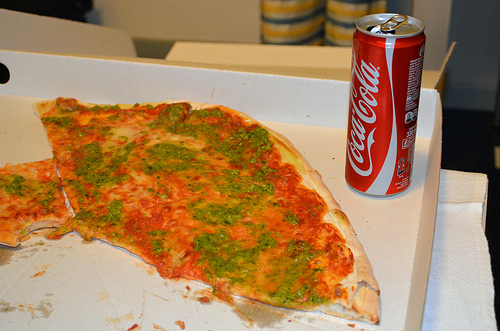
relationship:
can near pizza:
[343, 9, 420, 199] [1, 97, 381, 327]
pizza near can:
[1, 97, 381, 327] [343, 9, 420, 199]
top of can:
[380, 10, 409, 35] [343, 9, 420, 199]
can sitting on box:
[343, 9, 420, 199] [1, 47, 446, 330]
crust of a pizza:
[319, 216, 389, 323] [1, 97, 381, 327]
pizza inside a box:
[1, 97, 381, 327] [1, 47, 446, 330]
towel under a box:
[419, 160, 495, 330] [1, 47, 446, 330]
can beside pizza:
[343, 9, 420, 199] [1, 97, 381, 327]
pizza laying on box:
[1, 97, 381, 327] [1, 47, 446, 330]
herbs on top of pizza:
[140, 143, 191, 176] [1, 97, 381, 327]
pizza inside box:
[1, 97, 381, 327] [1, 47, 446, 330]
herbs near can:
[140, 143, 191, 176] [343, 9, 420, 199]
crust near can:
[319, 216, 389, 323] [343, 9, 420, 199]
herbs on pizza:
[140, 143, 191, 176] [1, 97, 381, 327]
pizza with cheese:
[1, 97, 381, 327] [109, 165, 229, 267]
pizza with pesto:
[1, 97, 381, 327] [156, 104, 270, 168]